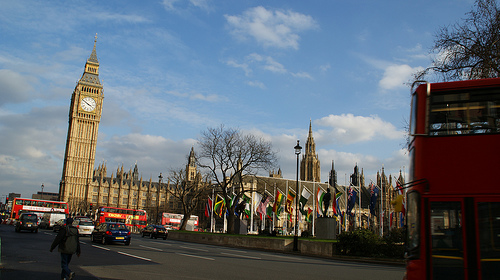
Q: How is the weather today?
A: It is cloudy.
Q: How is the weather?
A: It is cloudy.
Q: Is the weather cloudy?
A: Yes, it is cloudy.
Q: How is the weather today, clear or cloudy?
A: It is cloudy.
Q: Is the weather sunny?
A: No, it is cloudy.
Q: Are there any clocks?
A: Yes, there is a clock.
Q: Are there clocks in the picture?
A: Yes, there is a clock.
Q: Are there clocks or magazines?
A: Yes, there is a clock.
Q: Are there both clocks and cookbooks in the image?
A: No, there is a clock but no cookbooks.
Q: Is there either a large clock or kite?
A: Yes, there is a large clock.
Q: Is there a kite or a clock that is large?
A: Yes, the clock is large.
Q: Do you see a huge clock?
A: Yes, there is a huge clock.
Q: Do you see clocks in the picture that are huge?
A: Yes, there is a clock that is huge.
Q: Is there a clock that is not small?
A: Yes, there is a huge clock.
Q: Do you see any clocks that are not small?
A: Yes, there is a huge clock.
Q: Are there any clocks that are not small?
A: Yes, there is a huge clock.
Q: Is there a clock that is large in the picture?
A: Yes, there is a large clock.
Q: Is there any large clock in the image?
A: Yes, there is a large clock.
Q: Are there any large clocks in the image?
A: Yes, there is a large clock.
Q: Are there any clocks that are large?
A: Yes, there is a clock that is large.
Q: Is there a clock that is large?
A: Yes, there is a clock that is large.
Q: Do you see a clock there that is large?
A: Yes, there is a clock that is large.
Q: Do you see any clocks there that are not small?
A: Yes, there is a large clock.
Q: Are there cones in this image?
A: No, there are no cones.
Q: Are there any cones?
A: No, there are no cones.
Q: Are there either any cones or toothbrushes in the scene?
A: No, there are no cones or toothbrushes.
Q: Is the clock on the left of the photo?
A: Yes, the clock is on the left of the image.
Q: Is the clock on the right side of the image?
A: No, the clock is on the left of the image.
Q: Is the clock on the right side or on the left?
A: The clock is on the left of the image.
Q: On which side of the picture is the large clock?
A: The clock is on the left of the image.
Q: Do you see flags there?
A: Yes, there is a flag.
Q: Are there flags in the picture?
A: Yes, there is a flag.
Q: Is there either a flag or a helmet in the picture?
A: Yes, there is a flag.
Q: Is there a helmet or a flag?
A: Yes, there is a flag.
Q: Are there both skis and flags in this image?
A: No, there is a flag but no skis.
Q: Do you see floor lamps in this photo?
A: No, there are no floor lamps.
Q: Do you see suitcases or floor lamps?
A: No, there are no floor lamps or suitcases.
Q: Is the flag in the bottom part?
A: Yes, the flag is in the bottom of the image.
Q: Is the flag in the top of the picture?
A: No, the flag is in the bottom of the image.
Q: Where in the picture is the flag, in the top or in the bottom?
A: The flag is in the bottom of the image.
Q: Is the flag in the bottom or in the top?
A: The flag is in the bottom of the image.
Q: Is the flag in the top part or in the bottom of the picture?
A: The flag is in the bottom of the image.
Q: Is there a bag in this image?
A: No, there are no bags.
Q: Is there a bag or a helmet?
A: No, there are no bags or helmets.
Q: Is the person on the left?
A: Yes, the person is on the left of the image.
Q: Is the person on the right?
A: No, the person is on the left of the image.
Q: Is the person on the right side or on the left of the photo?
A: The person is on the left of the image.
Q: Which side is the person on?
A: The person is on the left of the image.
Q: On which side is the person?
A: The person is on the left of the image.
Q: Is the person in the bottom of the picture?
A: Yes, the person is in the bottom of the image.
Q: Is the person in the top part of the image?
A: No, the person is in the bottom of the image.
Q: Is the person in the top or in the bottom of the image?
A: The person is in the bottom of the image.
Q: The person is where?
A: The person is on the road.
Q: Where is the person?
A: The person is on the road.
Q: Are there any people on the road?
A: Yes, there is a person on the road.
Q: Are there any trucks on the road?
A: No, there is a person on the road.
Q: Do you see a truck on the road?
A: No, there is a person on the road.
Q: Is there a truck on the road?
A: No, there is a person on the road.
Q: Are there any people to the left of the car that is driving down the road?
A: Yes, there is a person to the left of the car.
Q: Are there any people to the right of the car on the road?
A: No, the person is to the left of the car.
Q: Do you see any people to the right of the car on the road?
A: No, the person is to the left of the car.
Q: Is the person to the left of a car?
A: Yes, the person is to the left of a car.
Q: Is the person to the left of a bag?
A: No, the person is to the left of a car.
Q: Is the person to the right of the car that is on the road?
A: No, the person is to the left of the car.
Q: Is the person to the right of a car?
A: No, the person is to the left of a car.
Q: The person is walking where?
A: The person is walking in the road.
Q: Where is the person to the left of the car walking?
A: The person is walking in the road.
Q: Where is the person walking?
A: The person is walking in the road.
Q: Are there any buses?
A: Yes, there is a bus.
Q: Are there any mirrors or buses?
A: Yes, there is a bus.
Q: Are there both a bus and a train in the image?
A: No, there is a bus but no trains.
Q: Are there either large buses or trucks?
A: Yes, there is a large bus.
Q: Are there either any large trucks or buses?
A: Yes, there is a large bus.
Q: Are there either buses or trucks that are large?
A: Yes, the bus is large.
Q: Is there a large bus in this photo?
A: Yes, there is a large bus.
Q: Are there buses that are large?
A: Yes, there is a bus that is large.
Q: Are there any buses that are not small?
A: Yes, there is a large bus.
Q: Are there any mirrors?
A: No, there are no mirrors.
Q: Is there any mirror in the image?
A: No, there are no mirrors.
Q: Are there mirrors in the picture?
A: No, there are no mirrors.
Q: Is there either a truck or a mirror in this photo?
A: No, there are no mirrors or trucks.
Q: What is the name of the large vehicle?
A: The vehicle is a bus.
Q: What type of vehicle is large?
A: The vehicle is a bus.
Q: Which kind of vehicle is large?
A: The vehicle is a bus.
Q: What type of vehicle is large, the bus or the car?
A: The bus is large.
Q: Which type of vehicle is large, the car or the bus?
A: The bus is large.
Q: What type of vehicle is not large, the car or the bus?
A: The car is not large.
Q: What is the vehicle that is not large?
A: The vehicle is a car.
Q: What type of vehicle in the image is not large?
A: The vehicle is a car.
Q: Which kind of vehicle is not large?
A: The vehicle is a car.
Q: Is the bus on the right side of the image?
A: Yes, the bus is on the right of the image.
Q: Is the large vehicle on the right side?
A: Yes, the bus is on the right of the image.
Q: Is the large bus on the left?
A: No, the bus is on the right of the image.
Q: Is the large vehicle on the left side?
A: No, the bus is on the right of the image.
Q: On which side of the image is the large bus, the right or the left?
A: The bus is on the right of the image.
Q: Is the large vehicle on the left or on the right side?
A: The bus is on the right of the image.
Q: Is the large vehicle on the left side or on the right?
A: The bus is on the right of the image.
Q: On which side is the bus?
A: The bus is on the right of the image.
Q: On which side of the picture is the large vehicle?
A: The bus is on the right of the image.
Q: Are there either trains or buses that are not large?
A: No, there is a bus but it is large.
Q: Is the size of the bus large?
A: Yes, the bus is large.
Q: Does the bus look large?
A: Yes, the bus is large.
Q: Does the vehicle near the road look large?
A: Yes, the bus is large.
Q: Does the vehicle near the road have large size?
A: Yes, the bus is large.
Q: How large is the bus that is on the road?
A: The bus is large.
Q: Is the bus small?
A: No, the bus is large.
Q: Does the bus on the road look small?
A: No, the bus is large.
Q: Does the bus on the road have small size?
A: No, the bus is large.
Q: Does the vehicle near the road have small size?
A: No, the bus is large.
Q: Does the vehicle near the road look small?
A: No, the bus is large.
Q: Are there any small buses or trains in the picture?
A: No, there is a bus but it is large.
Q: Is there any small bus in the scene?
A: No, there is a bus but it is large.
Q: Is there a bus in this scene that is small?
A: No, there is a bus but it is large.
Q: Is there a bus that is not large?
A: No, there is a bus but it is large.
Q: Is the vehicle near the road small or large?
A: The bus is large.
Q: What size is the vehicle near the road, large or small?
A: The bus is large.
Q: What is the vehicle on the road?
A: The vehicle is a bus.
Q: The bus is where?
A: The bus is on the road.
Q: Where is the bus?
A: The bus is on the road.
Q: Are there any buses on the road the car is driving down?
A: Yes, there is a bus on the road.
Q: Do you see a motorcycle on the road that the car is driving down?
A: No, there is a bus on the road.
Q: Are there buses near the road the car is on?
A: Yes, there is a bus near the road.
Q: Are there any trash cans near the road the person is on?
A: No, there is a bus near the road.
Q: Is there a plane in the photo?
A: No, there are no airplanes.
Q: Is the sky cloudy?
A: Yes, the sky is cloudy.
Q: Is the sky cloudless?
A: No, the sky is cloudy.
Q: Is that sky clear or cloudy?
A: The sky is cloudy.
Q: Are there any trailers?
A: No, there are no trailers.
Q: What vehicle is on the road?
A: The vehicle is a car.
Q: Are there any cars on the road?
A: Yes, there is a car on the road.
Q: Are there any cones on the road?
A: No, there is a car on the road.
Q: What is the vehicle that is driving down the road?
A: The vehicle is a car.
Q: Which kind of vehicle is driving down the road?
A: The vehicle is a car.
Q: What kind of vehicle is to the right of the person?
A: The vehicle is a car.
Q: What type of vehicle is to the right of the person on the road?
A: The vehicle is a car.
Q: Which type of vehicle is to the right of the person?
A: The vehicle is a car.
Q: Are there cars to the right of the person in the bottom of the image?
A: Yes, there is a car to the right of the person.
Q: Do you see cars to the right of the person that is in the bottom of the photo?
A: Yes, there is a car to the right of the person.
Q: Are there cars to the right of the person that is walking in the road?
A: Yes, there is a car to the right of the person.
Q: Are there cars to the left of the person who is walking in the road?
A: No, the car is to the right of the person.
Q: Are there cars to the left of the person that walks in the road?
A: No, the car is to the right of the person.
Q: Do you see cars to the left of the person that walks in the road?
A: No, the car is to the right of the person.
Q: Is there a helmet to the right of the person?
A: No, there is a car to the right of the person.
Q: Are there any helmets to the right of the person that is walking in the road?
A: No, there is a car to the right of the person.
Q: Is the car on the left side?
A: Yes, the car is on the left of the image.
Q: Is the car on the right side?
A: No, the car is on the left of the image.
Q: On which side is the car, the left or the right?
A: The car is on the left of the image.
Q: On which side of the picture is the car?
A: The car is on the left of the image.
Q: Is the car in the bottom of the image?
A: Yes, the car is in the bottom of the image.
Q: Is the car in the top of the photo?
A: No, the car is in the bottom of the image.